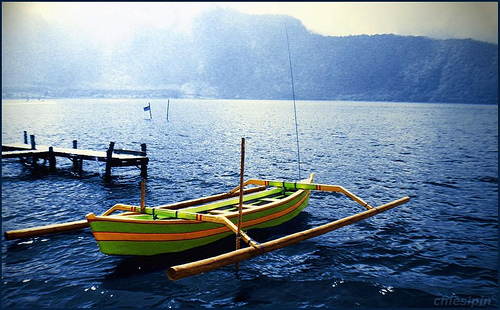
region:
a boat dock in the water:
[0, 120, 167, 190]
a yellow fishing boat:
[0, 137, 453, 289]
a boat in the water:
[1, 140, 439, 285]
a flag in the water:
[133, 94, 186, 132]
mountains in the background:
[0, 1, 499, 122]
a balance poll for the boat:
[130, 182, 433, 284]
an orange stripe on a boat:
[59, 165, 340, 262]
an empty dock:
[3, 117, 164, 193]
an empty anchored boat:
[3, 137, 423, 287]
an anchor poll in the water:
[223, 125, 261, 300]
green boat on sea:
[110, 141, 310, 299]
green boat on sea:
[32, 117, 232, 257]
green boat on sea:
[54, 154, 198, 301]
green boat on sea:
[107, 144, 214, 275]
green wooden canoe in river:
[38, 135, 370, 273]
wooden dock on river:
[7, 118, 149, 178]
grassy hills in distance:
[238, 15, 474, 122]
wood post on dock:
[101, 136, 114, 180]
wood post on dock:
[138, 140, 153, 174]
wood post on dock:
[42, 141, 58, 170]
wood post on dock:
[28, 132, 38, 162]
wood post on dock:
[18, 129, 26, 140]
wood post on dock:
[63, 135, 81, 148]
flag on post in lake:
[136, 100, 158, 120]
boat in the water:
[83, 172, 370, 277]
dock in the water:
[10, 127, 161, 181]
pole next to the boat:
[230, 137, 260, 256]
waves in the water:
[333, 260, 413, 296]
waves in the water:
[41, 256, 104, 306]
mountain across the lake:
[240, 21, 451, 91]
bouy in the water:
[135, 93, 160, 120]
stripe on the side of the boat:
[96, 220, 202, 250]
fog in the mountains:
[45, 16, 193, 76]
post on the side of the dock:
[105, 140, 130, 177]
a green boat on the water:
[83, 169, 323, 260]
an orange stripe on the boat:
[90, 173, 320, 247]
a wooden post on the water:
[97, 135, 122, 183]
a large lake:
[0, 99, 492, 309]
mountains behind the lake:
[0, 2, 499, 105]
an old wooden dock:
[2, 137, 152, 170]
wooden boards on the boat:
[2, 165, 421, 282]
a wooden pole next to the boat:
[223, 129, 250, 276]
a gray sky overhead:
[221, 0, 497, 40]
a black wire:
[283, 22, 306, 181]